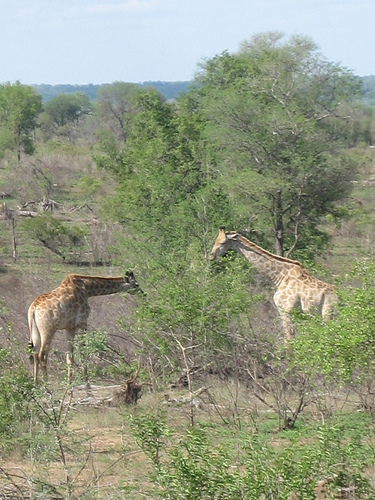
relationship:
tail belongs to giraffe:
[30, 298, 38, 363] [25, 270, 148, 403]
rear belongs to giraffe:
[26, 303, 49, 332] [25, 270, 148, 403]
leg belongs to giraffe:
[63, 329, 76, 404] [25, 270, 148, 403]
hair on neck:
[67, 274, 126, 282] [74, 273, 125, 298]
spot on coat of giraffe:
[44, 301, 54, 309] [25, 270, 148, 403]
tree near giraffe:
[78, 32, 371, 369] [206, 225, 352, 386]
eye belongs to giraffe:
[132, 280, 136, 288] [25, 270, 148, 403]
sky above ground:
[2, 2, 375, 87] [0, 96, 374, 500]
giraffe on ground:
[25, 270, 148, 403] [0, 96, 374, 500]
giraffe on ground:
[206, 225, 352, 386] [0, 96, 374, 500]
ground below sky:
[0, 96, 374, 500] [2, 2, 375, 87]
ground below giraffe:
[0, 96, 374, 500] [25, 270, 148, 403]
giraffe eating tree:
[206, 225, 352, 386] [78, 32, 371, 369]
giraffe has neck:
[206, 225, 352, 386] [74, 273, 125, 298]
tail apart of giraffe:
[30, 298, 38, 363] [25, 270, 148, 403]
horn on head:
[122, 270, 135, 280] [120, 271, 148, 302]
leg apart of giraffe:
[63, 329, 76, 404] [25, 270, 148, 403]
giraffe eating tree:
[25, 270, 148, 403] [78, 32, 371, 369]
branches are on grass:
[46, 330, 367, 433] [1, 377, 374, 500]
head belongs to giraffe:
[120, 271, 148, 302] [25, 270, 148, 403]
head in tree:
[120, 271, 148, 302] [78, 32, 371, 369]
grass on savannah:
[1, 377, 374, 500] [2, 31, 374, 499]